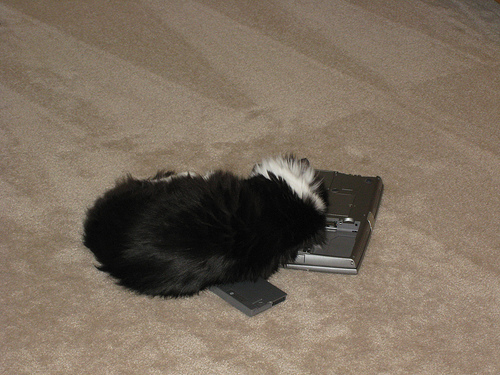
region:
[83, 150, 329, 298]
the dog on the carpet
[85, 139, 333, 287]
dog on the laptop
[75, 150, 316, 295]
the dog is black and white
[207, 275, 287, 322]
the battery pack under the dog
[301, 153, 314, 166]
the nose of the dog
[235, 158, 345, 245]
the head of the dog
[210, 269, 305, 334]
the battery pack out of the laptop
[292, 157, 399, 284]
the laptop on the carpet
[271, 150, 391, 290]
the laptop is off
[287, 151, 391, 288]
the laptop is closed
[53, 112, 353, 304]
a black and white cat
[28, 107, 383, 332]
a sleeping cat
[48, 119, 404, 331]
a cat on a floor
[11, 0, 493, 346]
tan carpeting on floor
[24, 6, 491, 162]
marks on floor from vacuum cleaner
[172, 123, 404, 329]
a laptop with the battery out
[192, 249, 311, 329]
battery to a laptop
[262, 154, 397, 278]
laptop without its battery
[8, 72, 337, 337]
a cat on a battery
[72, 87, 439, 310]
a cat on a laptop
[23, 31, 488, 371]
A cat is in somebody's house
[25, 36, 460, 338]
The cat is inside a room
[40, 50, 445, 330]
The cat is sleeping on a carpet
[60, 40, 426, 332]
The cat is taking a nap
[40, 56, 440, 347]
A cat is getting some rest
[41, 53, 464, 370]
A cat is waiting for its master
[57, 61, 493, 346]
A cat is waiting to be fed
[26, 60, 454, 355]
A cat is on an electronic device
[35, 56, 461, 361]
A cat is out in the daytime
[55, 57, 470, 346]
A cat is enjoying the day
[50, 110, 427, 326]
A cat sleeping on some electronics.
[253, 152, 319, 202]
This part of the cat is white.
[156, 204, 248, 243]
The cat's fur is mostly black.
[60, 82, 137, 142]
The carpet is plush and beige.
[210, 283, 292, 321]
A cell phone on the floor.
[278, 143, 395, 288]
A laptop on the floor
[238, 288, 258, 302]
The phone case is gray.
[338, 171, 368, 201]
The laptop case is gray.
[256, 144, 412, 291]
The laptop is upside down.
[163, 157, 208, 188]
The cat's leg is white.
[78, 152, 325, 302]
animal sits on electronic device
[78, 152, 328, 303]
animal sleeps on carpet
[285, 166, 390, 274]
electric device is underneath animal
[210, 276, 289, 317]
electric device is underneath animal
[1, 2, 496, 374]
carpet is underneath animal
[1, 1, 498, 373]
carpet is very clean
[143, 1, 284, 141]
marks indicate carpet has been vaccumed recently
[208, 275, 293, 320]
electronic device is halfway under animal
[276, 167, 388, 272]
electronic device is upside down